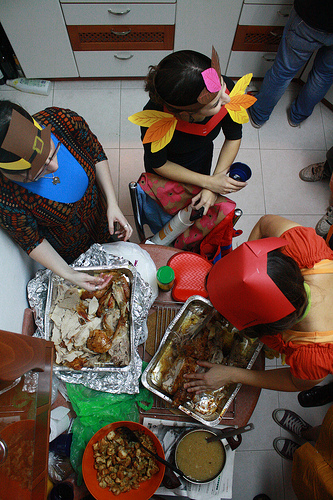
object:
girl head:
[145, 48, 230, 121]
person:
[266, 403, 333, 495]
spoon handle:
[138, 441, 184, 476]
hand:
[183, 359, 232, 394]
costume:
[126, 48, 256, 176]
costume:
[0, 105, 108, 253]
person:
[176, 212, 333, 405]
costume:
[207, 225, 333, 383]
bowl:
[170, 428, 225, 483]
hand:
[107, 205, 134, 242]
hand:
[69, 271, 113, 293]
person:
[0, 95, 131, 291]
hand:
[207, 166, 248, 193]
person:
[136, 48, 249, 217]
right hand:
[205, 166, 248, 195]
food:
[98, 431, 157, 484]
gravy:
[175, 431, 223, 479]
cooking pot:
[175, 426, 255, 485]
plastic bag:
[66, 361, 154, 492]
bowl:
[80, 422, 164, 498]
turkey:
[49, 273, 130, 367]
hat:
[205, 238, 296, 332]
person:
[252, 6, 333, 128]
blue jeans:
[254, 10, 332, 119]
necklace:
[42, 167, 61, 186]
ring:
[229, 190, 232, 194]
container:
[156, 265, 176, 291]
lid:
[156, 266, 174, 283]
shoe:
[272, 408, 310, 438]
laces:
[283, 414, 303, 433]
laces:
[286, 442, 298, 457]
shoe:
[271, 434, 298, 458]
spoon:
[114, 425, 183, 477]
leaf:
[127, 109, 174, 127]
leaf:
[230, 73, 253, 100]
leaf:
[226, 104, 249, 124]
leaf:
[150, 118, 177, 153]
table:
[47, 244, 266, 497]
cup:
[214, 158, 263, 176]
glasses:
[32, 141, 61, 181]